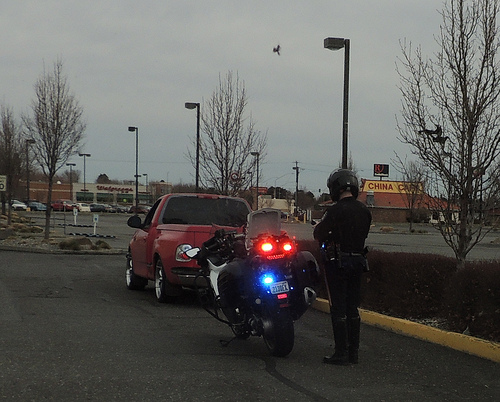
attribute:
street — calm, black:
[4, 253, 499, 401]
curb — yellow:
[309, 296, 499, 368]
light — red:
[262, 243, 272, 255]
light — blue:
[262, 274, 273, 289]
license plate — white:
[270, 280, 290, 295]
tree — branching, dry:
[397, 0, 500, 278]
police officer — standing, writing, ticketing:
[312, 170, 370, 362]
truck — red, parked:
[123, 193, 254, 308]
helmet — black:
[325, 165, 360, 203]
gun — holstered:
[362, 245, 370, 271]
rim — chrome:
[155, 263, 165, 296]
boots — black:
[324, 315, 362, 366]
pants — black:
[322, 255, 367, 316]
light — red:
[282, 242, 295, 254]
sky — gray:
[1, 0, 500, 197]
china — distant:
[369, 183, 392, 190]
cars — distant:
[9, 198, 150, 216]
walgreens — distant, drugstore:
[72, 181, 153, 208]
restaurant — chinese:
[320, 181, 463, 225]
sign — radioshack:
[373, 164, 388, 178]